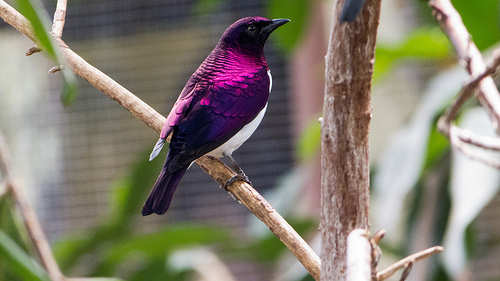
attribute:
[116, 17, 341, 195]
bird — small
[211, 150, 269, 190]
leg — thin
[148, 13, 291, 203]
bird — small, purple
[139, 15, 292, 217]
bird — purple, pink, small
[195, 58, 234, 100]
feathers — shiny, purple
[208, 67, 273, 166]
breast — white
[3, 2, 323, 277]
branch — thin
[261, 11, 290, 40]
beak — black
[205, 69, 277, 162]
chest — white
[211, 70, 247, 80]
feather — pink and purple